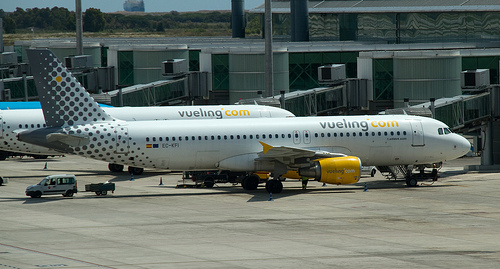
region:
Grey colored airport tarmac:
[119, 208, 254, 260]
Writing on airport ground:
[23, 254, 66, 267]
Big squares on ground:
[38, 210, 194, 255]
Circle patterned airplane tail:
[20, 45, 104, 120]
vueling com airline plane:
[174, 101, 257, 123]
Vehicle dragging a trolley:
[22, 170, 121, 205]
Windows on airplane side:
[186, 133, 256, 141]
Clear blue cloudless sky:
[174, 3, 208, 10]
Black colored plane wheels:
[263, 176, 285, 194]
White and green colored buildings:
[199, 43, 466, 67]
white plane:
[35, 38, 465, 200]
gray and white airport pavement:
[100, 216, 148, 243]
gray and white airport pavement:
[332, 236, 366, 253]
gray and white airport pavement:
[405, 212, 445, 252]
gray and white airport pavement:
[282, 216, 327, 244]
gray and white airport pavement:
[151, 196, 232, 241]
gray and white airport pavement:
[362, 218, 402, 248]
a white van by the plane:
[26, 175, 83, 195]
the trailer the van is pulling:
[82, 178, 118, 190]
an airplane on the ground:
[17, 48, 482, 190]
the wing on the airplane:
[226, 137, 362, 190]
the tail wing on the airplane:
[17, 45, 107, 145]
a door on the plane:
[407, 120, 424, 145]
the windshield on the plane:
[438, 125, 449, 134]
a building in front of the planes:
[72, 47, 497, 110]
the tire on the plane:
[401, 170, 422, 190]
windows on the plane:
[141, 134, 298, 140]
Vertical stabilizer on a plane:
[24, 43, 110, 125]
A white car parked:
[22, 175, 80, 198]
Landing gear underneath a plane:
[236, 176, 285, 190]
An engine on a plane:
[296, 153, 364, 185]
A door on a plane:
[408, 115, 425, 147]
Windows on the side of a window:
[143, 130, 410, 145]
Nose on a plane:
[451, 123, 471, 163]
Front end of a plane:
[365, 112, 477, 187]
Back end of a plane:
[16, 45, 197, 175]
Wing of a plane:
[252, 140, 342, 162]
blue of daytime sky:
[2, 0, 257, 18]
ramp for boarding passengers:
[405, 84, 492, 129]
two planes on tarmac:
[0, 46, 471, 193]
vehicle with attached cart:
[25, 173, 115, 201]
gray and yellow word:
[319, 115, 396, 135]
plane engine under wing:
[264, 146, 362, 184]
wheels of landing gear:
[242, 174, 284, 194]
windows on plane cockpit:
[435, 126, 454, 137]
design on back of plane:
[19, 47, 146, 167]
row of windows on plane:
[144, 129, 409, 141]